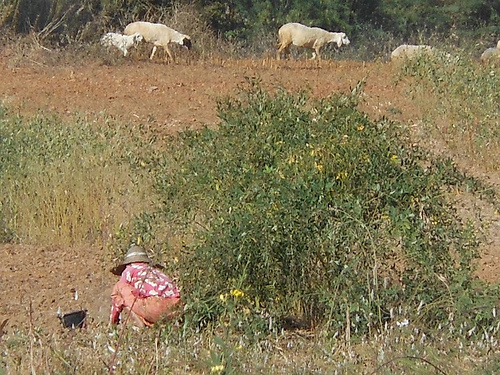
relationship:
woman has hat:
[97, 243, 181, 338] [108, 241, 168, 275]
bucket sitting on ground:
[55, 308, 92, 331] [0, 57, 496, 374]